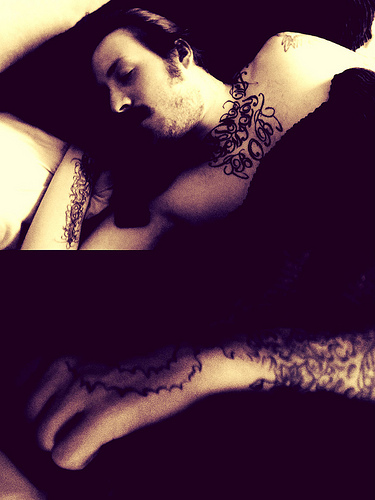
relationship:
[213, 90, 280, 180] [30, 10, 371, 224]
tattoo on man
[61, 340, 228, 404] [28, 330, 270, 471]
tattoo on top of hand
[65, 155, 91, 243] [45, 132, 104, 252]
tattoo on wrist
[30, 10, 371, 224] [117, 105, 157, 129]
man has a mustache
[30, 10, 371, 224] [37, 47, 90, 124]
man sleeping on top of pillow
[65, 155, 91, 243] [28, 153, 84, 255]
tattoo on arm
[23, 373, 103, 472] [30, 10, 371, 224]
fingers of man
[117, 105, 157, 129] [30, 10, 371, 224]
mustache on man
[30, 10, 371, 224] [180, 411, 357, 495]
man arm above blanket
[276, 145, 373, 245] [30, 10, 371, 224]
blanket on top of man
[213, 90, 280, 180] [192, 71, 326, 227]
tattoo on chest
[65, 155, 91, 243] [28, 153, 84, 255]
tattoo on forearm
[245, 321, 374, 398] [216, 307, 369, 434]
tattoo on outer forearm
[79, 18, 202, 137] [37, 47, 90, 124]
head on top of pillow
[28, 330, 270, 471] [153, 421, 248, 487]
hand on top of bedcover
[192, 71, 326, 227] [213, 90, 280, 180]
chest has a tattoo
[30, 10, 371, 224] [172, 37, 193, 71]
man has a ear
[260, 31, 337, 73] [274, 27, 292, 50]
shoulder has a tattoo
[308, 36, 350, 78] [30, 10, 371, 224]
sun on man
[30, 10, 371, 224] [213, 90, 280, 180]
man has tattoo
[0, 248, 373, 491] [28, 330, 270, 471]
close up of mans left hand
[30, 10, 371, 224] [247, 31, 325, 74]
man has a shoulder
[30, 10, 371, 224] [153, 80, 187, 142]
man has a beard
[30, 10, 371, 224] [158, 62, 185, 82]
man has a side burn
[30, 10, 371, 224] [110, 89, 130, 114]
man has a nose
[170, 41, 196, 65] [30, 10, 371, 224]
ear of man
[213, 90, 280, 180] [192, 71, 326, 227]
tattoo on top of chest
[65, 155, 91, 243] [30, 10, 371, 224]
tattoo on arm of man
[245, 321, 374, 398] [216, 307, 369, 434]
tattoo on forearm